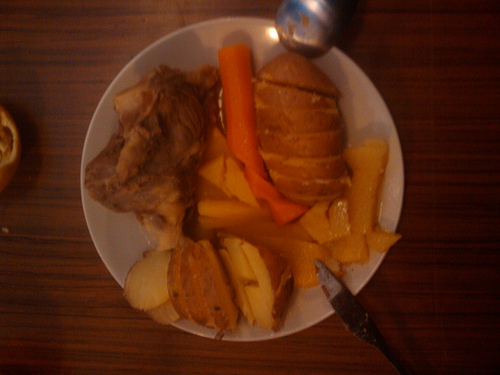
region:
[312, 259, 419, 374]
this is a knife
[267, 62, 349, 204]
This are slices of bread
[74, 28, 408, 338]
This is a white plate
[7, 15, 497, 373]
This is a table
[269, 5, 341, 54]
This is a scooping spoon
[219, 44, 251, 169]
This is a carrot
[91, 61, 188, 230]
This is apiece of meat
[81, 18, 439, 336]
This plate is full with food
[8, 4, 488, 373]
This table is brown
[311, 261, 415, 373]
This is a dirty knife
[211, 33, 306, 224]
The carrot on the plate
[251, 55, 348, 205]
The sliced potato the looks whole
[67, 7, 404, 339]
The white plate on the table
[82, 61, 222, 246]
The meat next to the carrot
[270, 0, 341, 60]
The silver spoon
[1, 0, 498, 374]
The wood table the plate is on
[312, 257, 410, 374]
The knife leaning on the plate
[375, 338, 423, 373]
The handle of the knife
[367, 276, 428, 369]
The shadow of the knife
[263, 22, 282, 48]
The light reflecting off the white plate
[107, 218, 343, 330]
The potatos are sliced.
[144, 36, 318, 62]
The plate is white.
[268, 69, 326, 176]
The bread is sliced.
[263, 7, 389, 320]
The plate has a knife and spoon.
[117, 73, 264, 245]
The meal has meat and vegitables.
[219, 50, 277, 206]
There are carrots on the plate.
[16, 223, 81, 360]
The plate is on a wooden table.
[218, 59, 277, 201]
The carrot is half-cut.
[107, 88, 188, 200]
The meat is not cut.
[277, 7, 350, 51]
The spoon is silver.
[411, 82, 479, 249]
The table is made of wood.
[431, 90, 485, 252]
The table is brown.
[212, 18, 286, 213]
The carrot is orange.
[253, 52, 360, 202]
The potato is brown.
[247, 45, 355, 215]
The potato has been sliced.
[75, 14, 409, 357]
The plate is round.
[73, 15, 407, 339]
The plate is white.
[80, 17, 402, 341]
The plate is made of plastic.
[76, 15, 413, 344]
Food is on the plate.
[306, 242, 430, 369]
The knife is gray.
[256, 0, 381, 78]
Spoon on serving plate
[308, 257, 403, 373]
Knife on serving plate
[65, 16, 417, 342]
White plate full of food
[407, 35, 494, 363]
Brown wooden table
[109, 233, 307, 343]
Sliced cooked potato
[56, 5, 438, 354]
Dinner meal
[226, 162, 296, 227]
Sliced cooked carrots on serving plate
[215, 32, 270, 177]
Cooked whole carrot on serving plate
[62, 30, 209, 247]
Meat serving on dinner plate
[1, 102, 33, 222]
Orange on wooden table